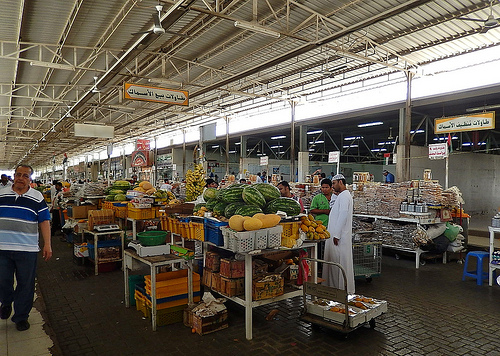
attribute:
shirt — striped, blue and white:
[0, 185, 50, 252]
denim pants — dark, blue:
[0, 249, 39, 324]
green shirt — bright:
[308, 183, 332, 226]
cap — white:
[331, 169, 348, 182]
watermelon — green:
[209, 181, 298, 220]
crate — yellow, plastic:
[143, 267, 202, 286]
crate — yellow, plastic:
[143, 281, 199, 290]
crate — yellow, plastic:
[142, 287, 202, 298]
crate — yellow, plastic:
[143, 299, 200, 313]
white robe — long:
[323, 189, 360, 292]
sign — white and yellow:
[118, 81, 188, 108]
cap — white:
[327, 171, 344, 181]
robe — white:
[325, 188, 356, 293]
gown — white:
[323, 189, 357, 294]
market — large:
[31, 141, 471, 336]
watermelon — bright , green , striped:
[253, 180, 282, 203]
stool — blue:
[147, 203, 464, 234]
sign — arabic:
[68, 57, 213, 109]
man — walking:
[6, 161, 53, 334]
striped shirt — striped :
[1, 182, 51, 255]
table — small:
[115, 248, 184, 323]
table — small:
[76, 222, 123, 271]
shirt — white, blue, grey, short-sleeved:
[0, 178, 61, 294]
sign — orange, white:
[127, 83, 192, 115]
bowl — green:
[130, 226, 173, 248]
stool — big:
[462, 246, 491, 284]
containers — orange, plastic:
[138, 265, 200, 302]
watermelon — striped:
[193, 178, 303, 219]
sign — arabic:
[112, 73, 199, 107]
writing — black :
[128, 85, 189, 106]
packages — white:
[302, 285, 387, 328]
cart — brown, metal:
[299, 254, 379, 335]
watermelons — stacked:
[204, 178, 301, 212]